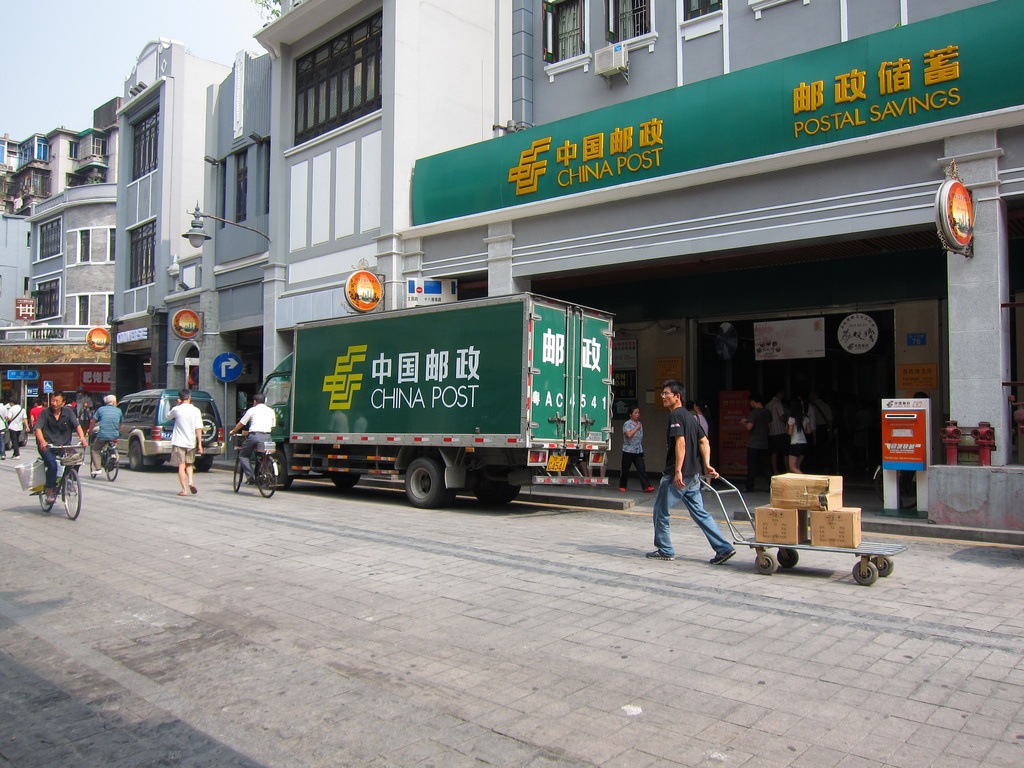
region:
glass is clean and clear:
[310, 144, 334, 244]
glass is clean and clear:
[286, 157, 305, 256]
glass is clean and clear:
[118, 220, 156, 281]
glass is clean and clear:
[693, 318, 754, 486]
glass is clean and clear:
[759, 363, 829, 493]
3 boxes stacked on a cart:
[749, 467, 867, 553]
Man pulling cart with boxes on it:
[641, 378, 737, 571]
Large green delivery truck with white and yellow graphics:
[235, 283, 622, 519]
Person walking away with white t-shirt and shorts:
[145, 380, 207, 507]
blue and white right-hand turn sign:
[202, 350, 245, 390]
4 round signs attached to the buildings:
[80, 169, 989, 353]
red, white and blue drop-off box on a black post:
[872, 393, 939, 483]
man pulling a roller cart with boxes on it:
[640, 373, 909, 596]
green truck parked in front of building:
[247, 285, 622, 516]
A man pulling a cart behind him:
[641, 373, 917, 612]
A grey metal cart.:
[706, 471, 903, 586]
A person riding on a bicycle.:
[17, 393, 101, 537]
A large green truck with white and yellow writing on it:
[217, 305, 632, 533]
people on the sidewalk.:
[602, 380, 929, 529]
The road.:
[18, 412, 1021, 763]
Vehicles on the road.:
[24, 297, 647, 564]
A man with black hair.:
[636, 371, 745, 575]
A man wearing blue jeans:
[650, 364, 740, 574]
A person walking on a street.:
[166, 384, 204, 496]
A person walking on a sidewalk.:
[618, 405, 656, 495]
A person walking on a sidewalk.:
[781, 403, 813, 474]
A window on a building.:
[546, 4, 586, 65]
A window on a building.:
[616, 0, 654, 45]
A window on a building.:
[294, 10, 383, 141]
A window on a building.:
[128, 215, 158, 288]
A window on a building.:
[130, 109, 157, 180]